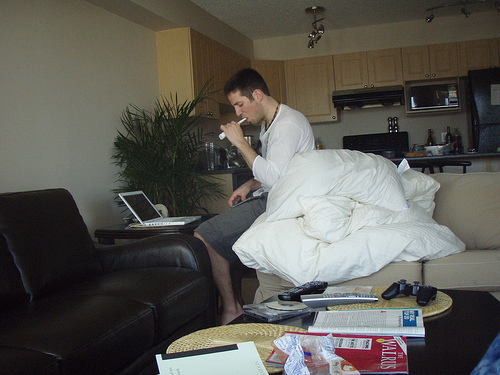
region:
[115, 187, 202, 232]
Open white laptop computer.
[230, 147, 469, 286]
Pile of white linens.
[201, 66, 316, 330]
Man sitting on the arm of a sofa.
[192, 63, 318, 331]
Man brushing his teeth.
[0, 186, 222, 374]
Dark colored leather sofa.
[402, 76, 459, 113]
Microwave oven.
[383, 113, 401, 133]
Salt and pepper shakers.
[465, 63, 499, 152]
Black refrigerator.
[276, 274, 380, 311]
A black and a silver remote control.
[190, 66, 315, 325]
Short haired man wearing shorts sitting on the edge of a sofa.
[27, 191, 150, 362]
the sofa is black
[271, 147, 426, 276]
the pillows are white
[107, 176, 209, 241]
the computer is white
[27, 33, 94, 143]
the wall is white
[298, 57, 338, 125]
the cabinet is brown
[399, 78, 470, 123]
the microwave is black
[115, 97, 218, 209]
the plant is green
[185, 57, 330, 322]
the person is male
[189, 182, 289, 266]
the shorts are gray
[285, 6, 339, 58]
the light is off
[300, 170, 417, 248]
A white down blanket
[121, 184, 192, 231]
A white laptop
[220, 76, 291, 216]
A man taking his temperature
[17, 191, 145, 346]
A black couch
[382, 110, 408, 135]
Silver salt and pepper shakers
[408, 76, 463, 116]
A microwave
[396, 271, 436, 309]
A remote to a gaming system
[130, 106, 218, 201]
A potted set of palms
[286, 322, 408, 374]
A red valrus magazine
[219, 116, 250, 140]
A white thermometer in a mans mouth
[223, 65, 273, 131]
the head of a man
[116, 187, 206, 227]
a white laptop computer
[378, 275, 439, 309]
a black game controller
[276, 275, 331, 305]
a black remote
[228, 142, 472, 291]
a pile of white pillows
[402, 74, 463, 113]
a microwave oven over the counter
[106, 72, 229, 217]
a large green plant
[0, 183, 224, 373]
a large black sofa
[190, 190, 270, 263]
a gray pair of shorts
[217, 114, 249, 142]
a white toothbrush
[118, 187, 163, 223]
The screen of the laptop.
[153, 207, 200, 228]
The keyboard area on the laptop.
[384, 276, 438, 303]
The black game controller on the table.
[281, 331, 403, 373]
The magazine with the red cover on the table.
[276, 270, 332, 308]
The black remote on the table.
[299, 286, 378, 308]
The gray remote on the table.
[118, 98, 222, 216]
The green plant in the corner.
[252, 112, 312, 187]
The white shirt the guy is wearing.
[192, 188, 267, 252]
The gray shorts the man is wearing.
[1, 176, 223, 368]
The black leather sofa.